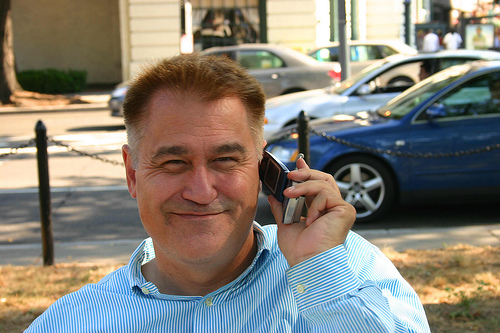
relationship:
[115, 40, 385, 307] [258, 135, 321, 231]
man on cell phone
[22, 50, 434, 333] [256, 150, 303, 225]
man on cell phone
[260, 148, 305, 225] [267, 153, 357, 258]
cell phone in hand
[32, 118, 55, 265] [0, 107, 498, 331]
post on ground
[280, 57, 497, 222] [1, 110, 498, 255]
blue car on street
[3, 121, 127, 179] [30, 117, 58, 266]
chain connected to pole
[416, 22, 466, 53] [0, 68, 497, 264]
people walking on street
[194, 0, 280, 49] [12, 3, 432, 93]
window in building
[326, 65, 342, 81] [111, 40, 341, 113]
taillight on car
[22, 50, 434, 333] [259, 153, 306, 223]
man talking on cell phone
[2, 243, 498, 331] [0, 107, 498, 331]
grass growing on ground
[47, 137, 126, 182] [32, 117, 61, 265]
chain connected to pole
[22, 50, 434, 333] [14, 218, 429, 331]
man wearing shirt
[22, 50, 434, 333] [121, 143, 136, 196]
man has ear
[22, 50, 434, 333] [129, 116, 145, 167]
man has hair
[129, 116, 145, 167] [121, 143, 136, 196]
hair around ear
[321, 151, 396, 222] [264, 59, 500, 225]
black tire on blue car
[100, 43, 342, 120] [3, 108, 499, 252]
car on road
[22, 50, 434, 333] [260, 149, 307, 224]
man talking on cellphone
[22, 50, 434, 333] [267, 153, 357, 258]
man has hand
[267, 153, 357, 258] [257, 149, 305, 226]
hand holding cell phone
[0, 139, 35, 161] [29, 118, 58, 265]
chain connected to post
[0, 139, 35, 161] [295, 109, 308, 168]
chain connected to post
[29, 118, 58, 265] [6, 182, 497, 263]
post beside road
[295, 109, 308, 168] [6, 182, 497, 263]
post beside road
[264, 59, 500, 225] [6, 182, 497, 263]
blue car in road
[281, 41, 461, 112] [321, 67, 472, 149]
car behind car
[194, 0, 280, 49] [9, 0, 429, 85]
window on building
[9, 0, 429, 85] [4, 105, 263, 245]
building across street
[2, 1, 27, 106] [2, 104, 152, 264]
tree trunk across street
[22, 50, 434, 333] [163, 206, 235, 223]
man has smile